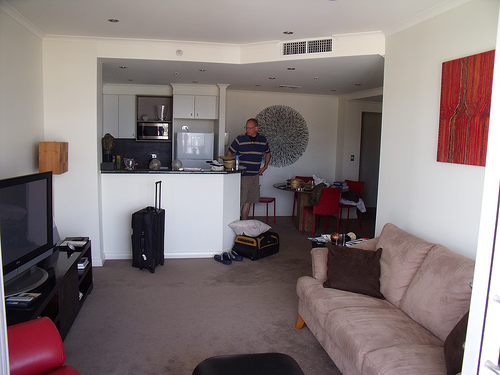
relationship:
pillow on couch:
[324, 245, 385, 300] [296, 223, 474, 374]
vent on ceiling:
[280, 39, 335, 55] [1, 1, 499, 39]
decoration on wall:
[253, 104, 309, 169] [229, 92, 339, 214]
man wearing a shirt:
[227, 119, 273, 222] [231, 134, 271, 176]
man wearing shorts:
[227, 119, 273, 222] [240, 175, 263, 206]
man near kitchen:
[227, 119, 273, 222] [104, 62, 243, 173]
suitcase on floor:
[132, 182, 166, 272] [71, 216, 380, 375]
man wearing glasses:
[227, 119, 273, 222] [243, 126, 261, 131]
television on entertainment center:
[1, 170, 54, 279] [5, 245, 91, 339]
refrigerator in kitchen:
[174, 131, 213, 169] [104, 62, 243, 173]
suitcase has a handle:
[132, 182, 166, 272] [152, 180, 162, 211]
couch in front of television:
[296, 223, 474, 374] [1, 170, 54, 279]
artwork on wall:
[435, 50, 492, 166] [376, 16, 497, 243]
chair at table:
[301, 187, 341, 235] [273, 181, 348, 232]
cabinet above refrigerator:
[196, 93, 221, 122] [174, 131, 213, 169]